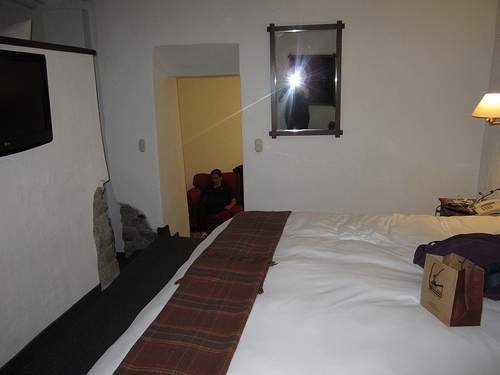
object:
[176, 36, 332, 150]
camera flash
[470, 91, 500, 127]
lamp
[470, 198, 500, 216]
phone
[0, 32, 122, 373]
wall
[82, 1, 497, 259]
wall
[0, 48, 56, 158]
tv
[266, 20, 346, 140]
mirror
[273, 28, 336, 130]
reflection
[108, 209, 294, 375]
blanket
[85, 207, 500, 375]
bedcover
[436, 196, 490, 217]
table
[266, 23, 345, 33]
frame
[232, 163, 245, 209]
person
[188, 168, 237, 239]
person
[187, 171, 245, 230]
sofa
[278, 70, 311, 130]
person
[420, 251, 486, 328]
shopping bag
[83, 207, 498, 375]
bed